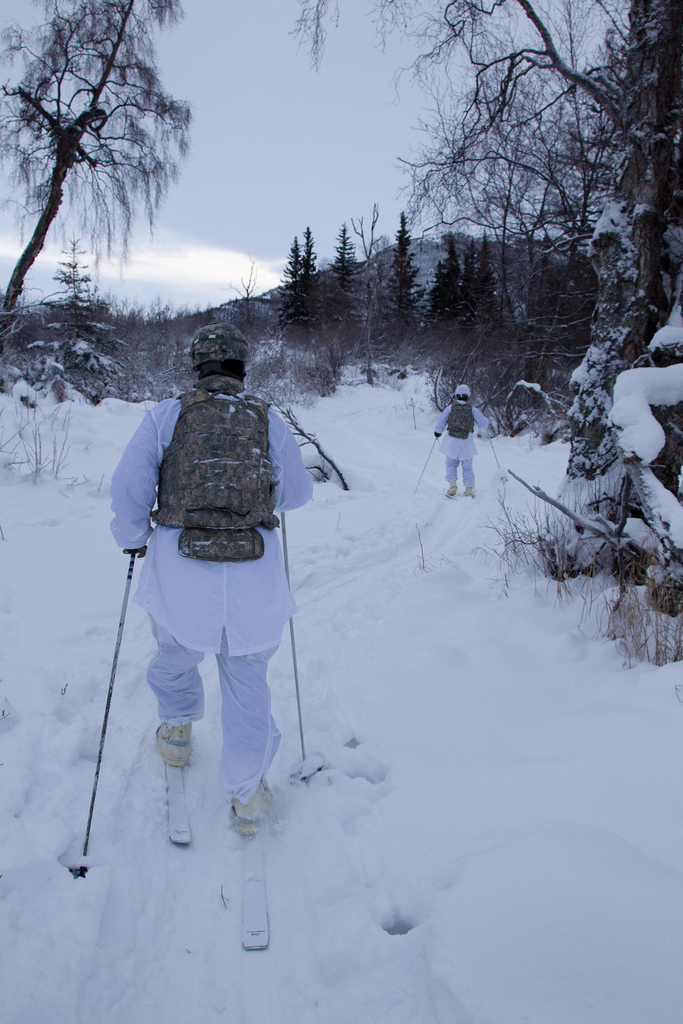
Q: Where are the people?
A: In the mountains.